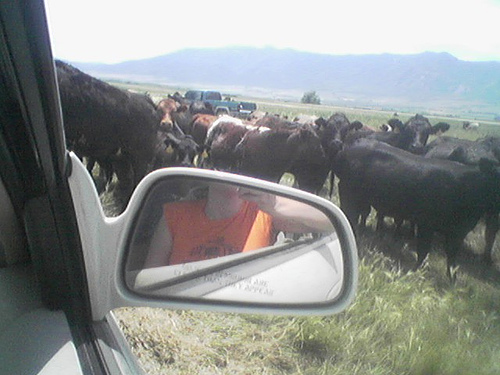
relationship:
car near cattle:
[3, 1, 355, 372] [50, 56, 499, 288]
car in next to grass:
[3, 1, 355, 372] [104, 194, 499, 372]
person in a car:
[143, 178, 270, 269] [3, 1, 355, 372]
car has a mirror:
[3, 1, 355, 372] [112, 163, 360, 314]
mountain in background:
[94, 45, 499, 123] [51, 0, 495, 131]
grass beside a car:
[104, 194, 499, 372] [3, 1, 355, 372]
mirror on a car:
[112, 163, 360, 314] [3, 1, 355, 372]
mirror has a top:
[112, 163, 360, 314] [123, 167, 352, 227]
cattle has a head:
[50, 56, 499, 288] [281, 124, 306, 160]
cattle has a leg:
[50, 56, 499, 288] [339, 178, 359, 232]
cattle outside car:
[50, 56, 499, 288] [3, 1, 355, 372]